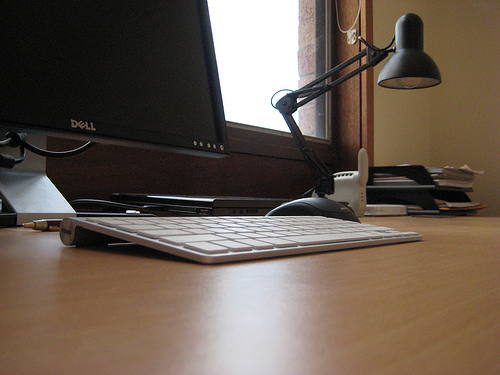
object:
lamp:
[264, 12, 441, 223]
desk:
[0, 215, 499, 374]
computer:
[0, 0, 244, 216]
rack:
[363, 159, 483, 212]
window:
[204, 0, 331, 142]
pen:
[18, 214, 64, 234]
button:
[189, 139, 199, 148]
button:
[198, 139, 206, 150]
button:
[204, 141, 212, 150]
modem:
[310, 147, 369, 217]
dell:
[66, 118, 104, 132]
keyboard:
[60, 213, 421, 265]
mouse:
[265, 194, 362, 225]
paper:
[441, 160, 486, 187]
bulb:
[395, 76, 422, 90]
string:
[331, 0, 369, 47]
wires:
[0, 134, 97, 166]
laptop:
[109, 190, 289, 215]